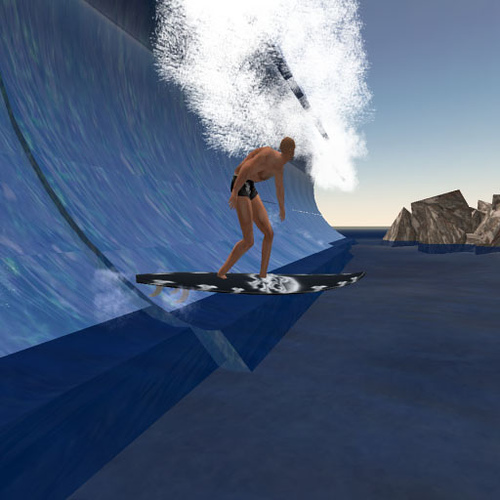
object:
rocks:
[382, 206, 421, 241]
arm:
[227, 148, 274, 210]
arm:
[275, 167, 286, 221]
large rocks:
[417, 205, 469, 255]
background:
[312, 0, 499, 226]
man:
[213, 136, 300, 285]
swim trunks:
[229, 173, 258, 201]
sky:
[308, 4, 498, 231]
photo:
[0, 0, 498, 498]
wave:
[150, 0, 377, 192]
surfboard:
[135, 271, 366, 296]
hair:
[280, 136, 296, 155]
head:
[279, 137, 296, 161]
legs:
[216, 196, 255, 279]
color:
[136, 271, 366, 296]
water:
[0, 226, 499, 498]